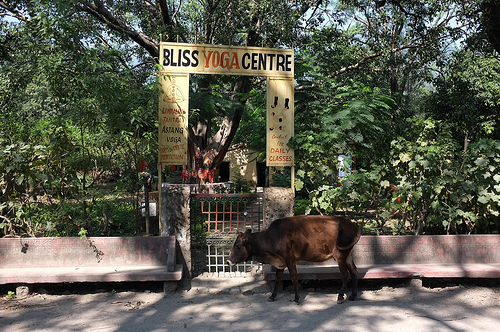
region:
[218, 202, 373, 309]
a cow is brown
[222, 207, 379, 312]
a cow is small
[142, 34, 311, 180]
a center of yoga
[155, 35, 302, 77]
center says "A bliss Yoga Center"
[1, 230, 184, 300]
benche of concrete is red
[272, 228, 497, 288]
bench of concrete is red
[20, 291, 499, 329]
shadows on grownd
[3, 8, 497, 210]
trees on back of benches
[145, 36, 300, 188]
entrance of Yoga Center is yellow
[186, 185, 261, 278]
a fence in front of Yoga Center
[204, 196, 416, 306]
cow standing on the ground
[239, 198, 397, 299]
the cow is brown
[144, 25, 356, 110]
bliss yoga centre sign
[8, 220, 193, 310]
bench to sit on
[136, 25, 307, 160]
the sign is yellow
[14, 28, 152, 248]
the trees have green leaves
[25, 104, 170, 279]
tree trunks made of wood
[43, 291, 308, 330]
the ground is cement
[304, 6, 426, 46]
the sky is clear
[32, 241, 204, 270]
the benches are brick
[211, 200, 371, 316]
A side view of an animal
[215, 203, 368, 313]
The animal is dark brown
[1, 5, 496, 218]
Trees are in the background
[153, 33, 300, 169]
A tan colored sign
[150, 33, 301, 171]
Sign is in the foreground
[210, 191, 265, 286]
A side view of the animal's head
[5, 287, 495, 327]
Trees are casting a shadow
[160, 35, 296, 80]
The sign says "Bliss Yoga Centre"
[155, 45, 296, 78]
The sign's fonts are in black and red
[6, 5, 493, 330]
Photo was taken outdoors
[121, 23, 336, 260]
the sign is yellow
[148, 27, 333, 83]
black and red letters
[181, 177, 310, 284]
the door is made of metal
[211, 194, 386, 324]
animal standing in front of sign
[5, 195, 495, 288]
concrete benches next to sign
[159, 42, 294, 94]
words say bliss yoga centre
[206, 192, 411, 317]
the animal is brown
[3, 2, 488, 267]
trees are behind the sign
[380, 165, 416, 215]
red object in trees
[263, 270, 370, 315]
animal's hooves are black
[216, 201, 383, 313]
Cow is standing in road.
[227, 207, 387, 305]
Cow is brown color.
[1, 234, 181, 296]
Bench is red color.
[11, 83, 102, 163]
Trees are green color.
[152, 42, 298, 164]
Board is yellow color.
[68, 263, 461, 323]
Shadow falls on road.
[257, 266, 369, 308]
Cow has four legs.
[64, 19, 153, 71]
Sky is blue color.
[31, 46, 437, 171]
Trees are behind the bench.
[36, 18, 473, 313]
Day time picture.